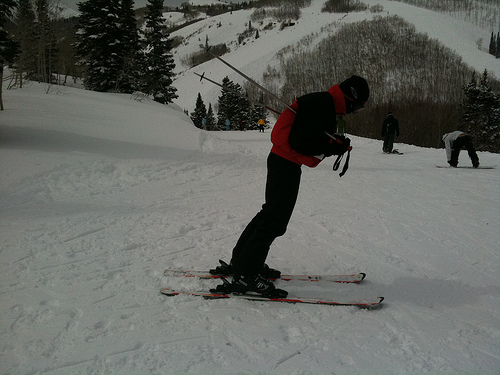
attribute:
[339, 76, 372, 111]
ski mask — black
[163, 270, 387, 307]
skis — red, black, white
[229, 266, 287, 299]
boots — black, white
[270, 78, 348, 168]
jacket — red, black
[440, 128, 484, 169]
person — bending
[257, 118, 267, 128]
jacket — yellow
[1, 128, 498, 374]
snow — white, snow covered, thick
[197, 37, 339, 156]
ski poles — set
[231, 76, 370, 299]
skier — leaning, skiing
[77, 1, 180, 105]
trees — snowy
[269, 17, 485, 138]
trees — bare